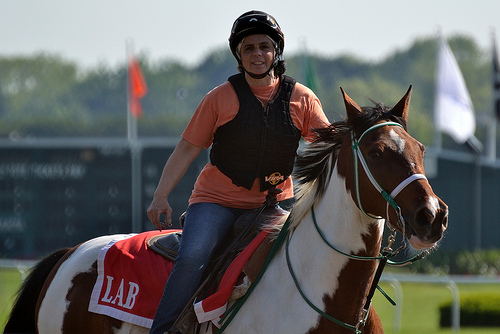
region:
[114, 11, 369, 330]
person riding on horse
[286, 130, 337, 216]
black and white mane of horse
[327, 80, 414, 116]
black perky ears of horse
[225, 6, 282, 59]
black riders helmet on head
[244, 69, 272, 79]
black chin strap of helmet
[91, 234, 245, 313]
red and white riding blanket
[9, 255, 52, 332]
black furry tail of horse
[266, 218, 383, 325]
neck straps around horse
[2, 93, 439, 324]
brown and white horse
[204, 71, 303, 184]
black safety vest on person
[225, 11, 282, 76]
Riding helmet on woman's head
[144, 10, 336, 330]
Woman riding a horse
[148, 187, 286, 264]
Saddle on the horse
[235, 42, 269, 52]
Glasses on the woman's face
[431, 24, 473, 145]
White flag in the background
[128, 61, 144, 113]
Red flag in the background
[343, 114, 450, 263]
Bridal on the horse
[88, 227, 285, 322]
Red and white blanket on horse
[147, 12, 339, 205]
Woman in orange shirt riding a horse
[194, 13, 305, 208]
Woman wearing black vest riding a horse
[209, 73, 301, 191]
A black vest.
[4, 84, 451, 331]
A brown and white horse.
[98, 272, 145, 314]
The word lab in white and capital letters.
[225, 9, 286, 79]
A dark helmet.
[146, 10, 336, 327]
A person riding a horse.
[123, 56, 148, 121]
A red flag.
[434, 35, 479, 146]
A white flag.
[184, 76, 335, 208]
A peach colored short sleeve shirt.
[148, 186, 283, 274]
A black saddle.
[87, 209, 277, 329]
A red and white horse blanket.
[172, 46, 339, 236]
man wearing orange shirt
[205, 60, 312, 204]
man wearing black vest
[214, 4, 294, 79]
man wearing helmet with hat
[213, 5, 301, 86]
helmet with strap is black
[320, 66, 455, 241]
horse has brown head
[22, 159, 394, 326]
horse body is brown and white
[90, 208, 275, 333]
horse wearing red material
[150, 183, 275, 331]
man wearing blue jeans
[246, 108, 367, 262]
horses mane is black and white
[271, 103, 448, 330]
horse has green bridle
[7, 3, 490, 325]
a person on a horse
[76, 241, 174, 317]
a red and white blanket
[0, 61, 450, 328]
a brown and white horse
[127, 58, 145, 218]
a pole with a red flag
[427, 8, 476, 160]
a pole with a white flag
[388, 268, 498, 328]
a white railing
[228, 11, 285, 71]
a black helmet on a head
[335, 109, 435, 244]
a white and green grear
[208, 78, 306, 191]
a black vest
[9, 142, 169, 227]
a score board in the back